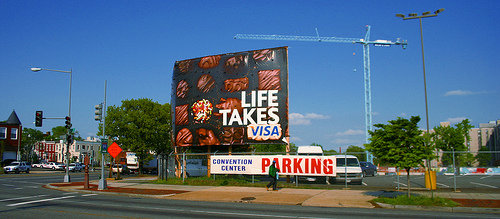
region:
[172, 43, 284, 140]
billboard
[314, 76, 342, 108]
white clouds in blue sky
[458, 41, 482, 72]
white clouds in blue sky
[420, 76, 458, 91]
white clouds in blue sky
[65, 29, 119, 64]
white clouds in blue sky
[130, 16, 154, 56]
white clouds in blue sky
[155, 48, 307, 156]
colorful billboard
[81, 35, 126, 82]
white clouds in blue sky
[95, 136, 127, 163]
red sign on street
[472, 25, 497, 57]
white clouds in blue sky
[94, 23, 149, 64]
white clouds in blue sky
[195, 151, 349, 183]
red and white sign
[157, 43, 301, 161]
billboard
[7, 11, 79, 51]
white clouds in blue sky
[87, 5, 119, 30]
white clouds in blue sky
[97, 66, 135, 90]
white clouds in blue sky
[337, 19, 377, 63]
white clouds in blue sky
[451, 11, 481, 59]
white clouds in blue sky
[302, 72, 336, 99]
white clouds in blue sky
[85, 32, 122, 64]
white clouds in blue sky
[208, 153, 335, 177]
a sign for parking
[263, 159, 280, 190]
a person is walking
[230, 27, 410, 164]
a large blue crane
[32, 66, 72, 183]
a metal street light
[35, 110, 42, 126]
light for an intersection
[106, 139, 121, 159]
an orange sign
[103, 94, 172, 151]
green leaves on a tree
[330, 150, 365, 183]
a white van is parked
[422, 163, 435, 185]
a yellow concrete base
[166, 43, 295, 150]
Billboard sign for Visa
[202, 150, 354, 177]
signage for Convention Center Parking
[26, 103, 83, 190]
Street light set at red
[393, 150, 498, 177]
Barriers at back side of parking lot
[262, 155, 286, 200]
man in green jacket walking past parking lot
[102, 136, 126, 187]
orange diamond shape street sign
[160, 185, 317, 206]
concrete ramp in sidewalk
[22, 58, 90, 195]
white street light behind traffic light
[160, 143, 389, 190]
multiple cars parked in parking lot